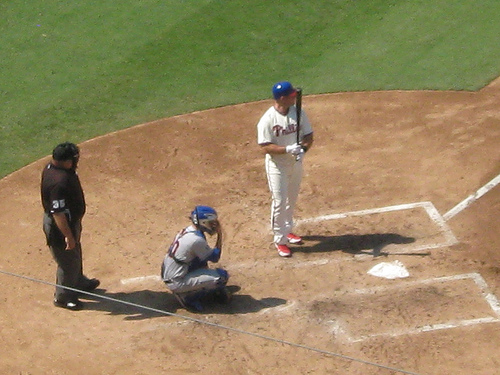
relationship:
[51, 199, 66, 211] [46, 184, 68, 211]
number on sleeve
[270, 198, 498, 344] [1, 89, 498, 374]
lines on ground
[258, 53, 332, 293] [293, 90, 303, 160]
man holding bat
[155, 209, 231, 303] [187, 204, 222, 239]
man touching helmet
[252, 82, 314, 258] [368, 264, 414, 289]
player at plate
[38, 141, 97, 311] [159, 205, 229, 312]
umpire standing behind catcher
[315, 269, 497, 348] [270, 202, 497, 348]
box marked with chalk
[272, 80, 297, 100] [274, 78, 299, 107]
helmet on head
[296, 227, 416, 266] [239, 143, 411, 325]
shadow in dirt